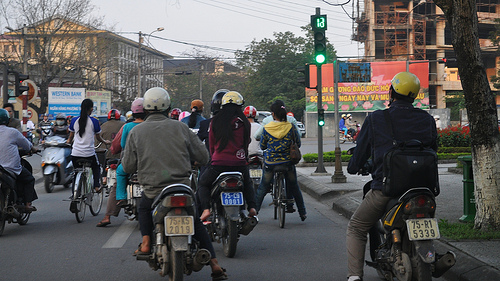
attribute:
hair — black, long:
[210, 107, 249, 150]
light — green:
[312, 49, 324, 64]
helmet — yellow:
[385, 82, 416, 104]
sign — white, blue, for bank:
[47, 80, 87, 124]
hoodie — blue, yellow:
[256, 127, 292, 170]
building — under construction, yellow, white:
[373, 6, 497, 138]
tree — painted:
[456, 8, 500, 234]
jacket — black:
[352, 100, 443, 190]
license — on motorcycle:
[412, 219, 436, 240]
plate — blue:
[219, 190, 245, 208]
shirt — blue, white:
[55, 118, 97, 159]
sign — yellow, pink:
[303, 78, 431, 112]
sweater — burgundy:
[201, 108, 259, 174]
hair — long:
[77, 97, 105, 140]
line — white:
[96, 222, 134, 257]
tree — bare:
[3, 4, 110, 85]